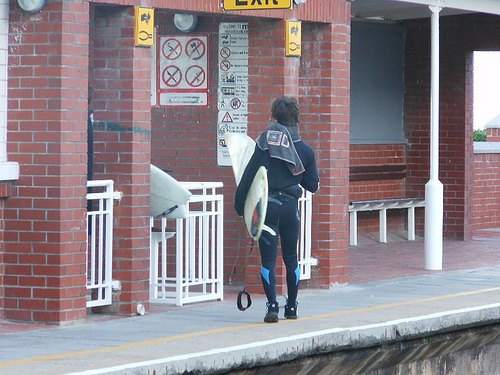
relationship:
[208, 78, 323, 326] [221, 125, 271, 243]
surfer with surfboard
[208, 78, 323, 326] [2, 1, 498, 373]
surfer at transportation station